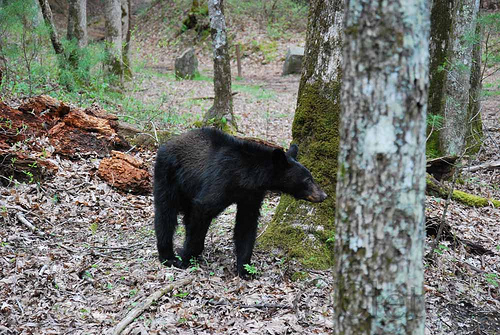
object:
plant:
[426, 0, 500, 185]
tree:
[426, 0, 483, 167]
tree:
[100, 0, 126, 89]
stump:
[174, 46, 199, 81]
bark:
[333, 36, 431, 317]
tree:
[333, 0, 432, 335]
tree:
[0, 90, 153, 196]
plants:
[0, 1, 74, 97]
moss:
[258, 14, 341, 281]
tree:
[39, 0, 75, 95]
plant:
[242, 263, 257, 276]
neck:
[240, 143, 283, 190]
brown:
[0, 94, 152, 194]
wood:
[18, 95, 61, 129]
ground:
[7, 60, 499, 326]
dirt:
[1, 65, 496, 325]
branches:
[1, 65, 496, 327]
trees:
[64, 0, 90, 87]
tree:
[199, 1, 240, 133]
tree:
[121, 0, 135, 80]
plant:
[256, 0, 341, 280]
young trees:
[1, 1, 108, 99]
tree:
[427, 11, 500, 257]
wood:
[0, 92, 44, 148]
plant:
[453, 190, 487, 208]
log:
[426, 152, 500, 207]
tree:
[267, 1, 315, 41]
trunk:
[255, 1, 342, 266]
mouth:
[306, 191, 329, 203]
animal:
[151, 126, 327, 281]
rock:
[282, 46, 304, 74]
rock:
[174, 46, 197, 79]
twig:
[44, 189, 65, 211]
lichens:
[255, 73, 337, 272]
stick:
[106, 273, 194, 333]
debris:
[107, 274, 193, 333]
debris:
[123, 269, 145, 287]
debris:
[94, 250, 127, 259]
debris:
[38, 265, 46, 278]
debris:
[91, 242, 143, 250]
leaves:
[0, 0, 500, 335]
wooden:
[35, 109, 144, 159]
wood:
[68, 0, 91, 87]